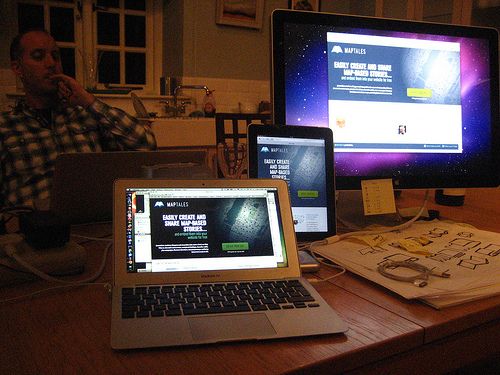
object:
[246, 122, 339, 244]
computer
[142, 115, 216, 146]
sink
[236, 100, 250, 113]
tea pot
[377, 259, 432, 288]
usb cord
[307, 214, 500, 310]
paper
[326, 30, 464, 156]
advertising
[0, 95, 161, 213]
shirt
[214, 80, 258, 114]
backsplash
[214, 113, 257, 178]
dining chair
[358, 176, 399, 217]
note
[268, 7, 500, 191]
computer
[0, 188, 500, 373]
table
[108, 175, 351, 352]
computers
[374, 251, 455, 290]
cables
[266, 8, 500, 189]
monitor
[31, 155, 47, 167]
plaid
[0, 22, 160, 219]
man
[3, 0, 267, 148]
kitchen